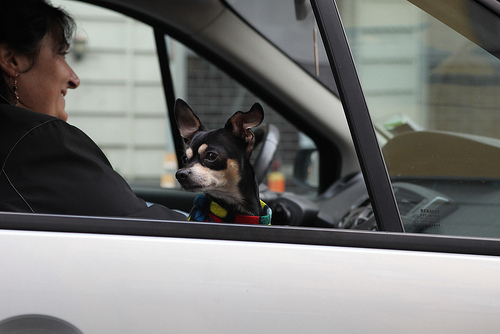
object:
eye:
[181, 154, 189, 163]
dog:
[173, 97, 265, 223]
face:
[7, 37, 81, 120]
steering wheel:
[247, 123, 282, 184]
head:
[173, 97, 265, 193]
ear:
[0, 43, 32, 76]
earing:
[13, 72, 22, 107]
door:
[0, 0, 497, 333]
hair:
[0, 0, 76, 105]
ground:
[345, 166, 363, 199]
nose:
[175, 167, 193, 182]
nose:
[67, 62, 81, 90]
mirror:
[293, 0, 307, 22]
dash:
[317, 180, 456, 234]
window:
[1, 1, 383, 232]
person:
[0, 1, 189, 221]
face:
[176, 140, 243, 191]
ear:
[223, 101, 265, 160]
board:
[415, 61, 496, 128]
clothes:
[187, 192, 272, 225]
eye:
[202, 151, 220, 162]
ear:
[172, 98, 209, 146]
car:
[1, 0, 499, 333]